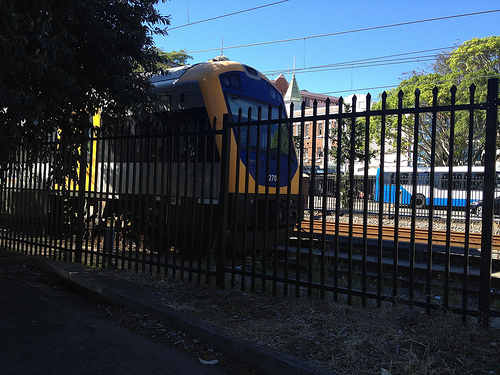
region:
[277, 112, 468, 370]
The fence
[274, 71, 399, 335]
The fence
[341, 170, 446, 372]
The fence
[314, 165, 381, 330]
The fence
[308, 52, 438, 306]
The fence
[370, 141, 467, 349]
The fence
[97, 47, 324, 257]
yellow and grey train on tracks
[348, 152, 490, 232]
white and blue bus in background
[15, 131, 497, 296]
iron fence in photograph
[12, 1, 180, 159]
many tree leaves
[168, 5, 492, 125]
many electrical wires in photograph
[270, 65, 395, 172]
brown and white building in background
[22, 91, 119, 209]
yellow door on side of silver train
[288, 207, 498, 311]
train tracks in photograph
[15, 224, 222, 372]
street visible in photograph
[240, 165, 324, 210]
white numbers on front of train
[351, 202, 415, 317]
The fence is visible.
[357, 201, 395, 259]
The fence is visible.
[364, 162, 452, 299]
The fence is visible.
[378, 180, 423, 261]
The fence is visible.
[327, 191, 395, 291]
The fence is visible.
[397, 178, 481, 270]
The fence is visible.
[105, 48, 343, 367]
the train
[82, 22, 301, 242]
the train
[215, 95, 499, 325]
A black fence.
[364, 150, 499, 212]
A blue and white.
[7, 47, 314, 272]
The train is yellow and blue.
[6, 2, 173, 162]
A tree is in the corner.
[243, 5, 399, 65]
Wires are overhead.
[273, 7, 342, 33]
The sky is clear.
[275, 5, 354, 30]
The sky is blue.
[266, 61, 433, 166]
Buildings are in the background.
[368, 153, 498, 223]
A bus is in the background.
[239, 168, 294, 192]
The train has a number on the front of it.